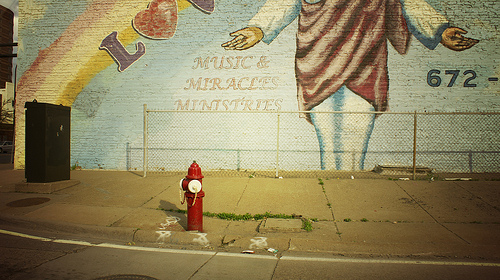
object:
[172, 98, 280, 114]
lettering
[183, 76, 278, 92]
lettering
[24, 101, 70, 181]
case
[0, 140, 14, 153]
car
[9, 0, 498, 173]
mural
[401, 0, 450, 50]
arm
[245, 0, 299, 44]
arm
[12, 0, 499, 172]
building exterior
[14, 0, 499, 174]
mural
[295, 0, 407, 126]
robe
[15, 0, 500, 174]
painting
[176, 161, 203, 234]
hydrant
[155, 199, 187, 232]
shadow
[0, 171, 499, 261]
pavement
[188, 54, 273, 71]
lettering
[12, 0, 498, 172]
wall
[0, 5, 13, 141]
building